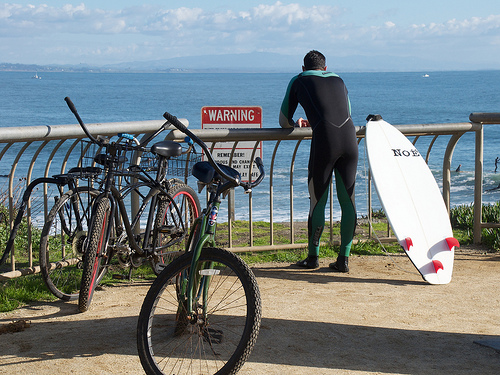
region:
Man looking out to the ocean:
[278, 50, 360, 273]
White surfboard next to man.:
[363, 111, 457, 284]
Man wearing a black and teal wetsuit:
[278, 49, 360, 272]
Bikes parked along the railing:
[39, 99, 203, 321]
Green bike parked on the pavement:
[136, 110, 266, 374]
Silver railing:
[0, 106, 499, 275]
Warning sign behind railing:
[200, 105, 263, 196]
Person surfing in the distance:
[493, 151, 498, 180]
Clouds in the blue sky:
[0, 0, 498, 70]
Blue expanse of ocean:
[0, 68, 499, 230]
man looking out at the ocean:
[268, 35, 372, 279]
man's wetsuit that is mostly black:
[271, 69, 369, 267]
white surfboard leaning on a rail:
[358, 105, 468, 292]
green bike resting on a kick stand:
[133, 103, 270, 374]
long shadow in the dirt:
[3, 296, 498, 373]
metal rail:
[1, 111, 499, 301]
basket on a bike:
[76, 135, 204, 193]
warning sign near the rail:
[198, 100, 270, 192]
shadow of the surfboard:
[234, 261, 429, 291]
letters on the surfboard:
[393, 145, 419, 162]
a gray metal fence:
[2, 113, 499, 285]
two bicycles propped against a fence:
[28, 93, 201, 312]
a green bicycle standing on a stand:
[135, 110, 264, 374]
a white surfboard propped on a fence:
[363, 112, 460, 285]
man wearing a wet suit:
[281, 73, 359, 260]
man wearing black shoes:
[291, 255, 351, 272]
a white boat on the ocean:
[32, 74, 41, 80]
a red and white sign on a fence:
[201, 105, 263, 186]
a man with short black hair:
[301, 50, 327, 71]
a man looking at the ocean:
[279, 48, 359, 272]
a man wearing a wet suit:
[271, 43, 368, 279]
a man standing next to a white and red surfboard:
[278, 45, 465, 290]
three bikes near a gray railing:
[24, 92, 286, 373]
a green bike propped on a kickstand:
[135, 107, 270, 373]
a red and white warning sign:
[196, 105, 271, 185]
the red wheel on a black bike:
[151, 185, 199, 281]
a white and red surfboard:
[360, 104, 463, 291]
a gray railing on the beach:
[2, 108, 498, 260]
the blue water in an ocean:
[3, 56, 498, 223]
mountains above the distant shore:
[99, 41, 499, 71]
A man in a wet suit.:
[277, 42, 360, 284]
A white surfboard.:
[363, 111, 460, 289]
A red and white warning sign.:
[202, 106, 262, 123]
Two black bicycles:
[38, 99, 200, 373]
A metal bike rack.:
[0, 123, 47, 313]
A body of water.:
[90, 77, 157, 115]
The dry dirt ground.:
[305, 281, 405, 322]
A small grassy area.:
[451, 201, 471, 232]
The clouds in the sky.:
[168, 2, 318, 47]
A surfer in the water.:
[490, 150, 499, 182]